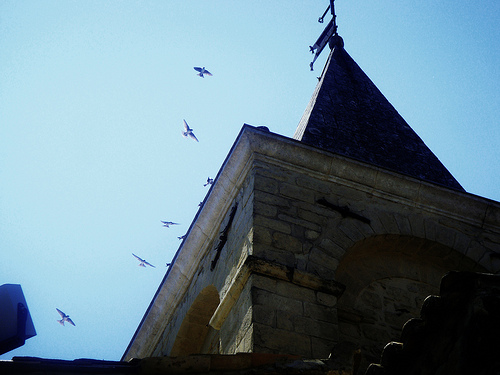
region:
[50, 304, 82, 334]
bird flying in the sky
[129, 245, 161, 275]
bird flying in the sky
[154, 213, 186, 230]
bird flying in the sky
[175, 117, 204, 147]
bird flying in the sky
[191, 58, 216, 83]
bird flying in the sky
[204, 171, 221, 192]
bird sitting on edge of building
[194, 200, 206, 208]
bird sitting on edge of building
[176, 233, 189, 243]
bird sitting on edge of building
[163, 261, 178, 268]
bird sitting on edge of building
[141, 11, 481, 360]
pointy top of building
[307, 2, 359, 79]
Flag on top of the building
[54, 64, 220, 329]
Flock of birds in the sky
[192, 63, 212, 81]
Bird in the sky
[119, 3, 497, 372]
Tall building beneath the birds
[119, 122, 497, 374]
Bottom half of the building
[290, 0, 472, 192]
Top half of the building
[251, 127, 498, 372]
One side of the building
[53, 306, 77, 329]
Bird in the back of the flock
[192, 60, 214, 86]
Bird in front of the flock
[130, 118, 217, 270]
Birds in the middle of the flock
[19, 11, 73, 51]
white clouds in blue sky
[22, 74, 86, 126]
white clouds in blue sky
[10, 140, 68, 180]
white clouds in blue sky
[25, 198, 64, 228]
white clouds in blue sky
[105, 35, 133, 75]
white clouds in blue sky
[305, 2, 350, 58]
flag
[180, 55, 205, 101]
flying black birds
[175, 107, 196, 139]
flying black birds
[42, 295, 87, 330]
flying black birds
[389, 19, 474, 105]
white clouds in blue sky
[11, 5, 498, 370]
the top of a stone building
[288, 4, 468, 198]
the steeple of the building is triangular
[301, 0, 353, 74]
an iron fixture is on top of the building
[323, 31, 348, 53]
a ball is on the tip of the building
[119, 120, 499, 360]
a parapet is on top of the building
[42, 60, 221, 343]
birds are flying around the building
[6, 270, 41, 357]
a light fixture is focused on the building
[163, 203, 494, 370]
arches are on the tower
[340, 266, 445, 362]
the arch is filled with cemented stones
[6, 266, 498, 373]
tiled roofs are below the tower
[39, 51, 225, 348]
Birds flying over a building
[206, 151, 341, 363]
The building is made of brick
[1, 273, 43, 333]
A light that shines on the building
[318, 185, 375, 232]
A metal brace of some kind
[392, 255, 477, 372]
The roof of a structure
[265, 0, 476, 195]
A tall pointed roof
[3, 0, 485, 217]
There are no clouds in this sky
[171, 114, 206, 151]
A bird with wings spread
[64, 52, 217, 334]
Many birds with wings spread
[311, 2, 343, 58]
A pole on the top of a steeple